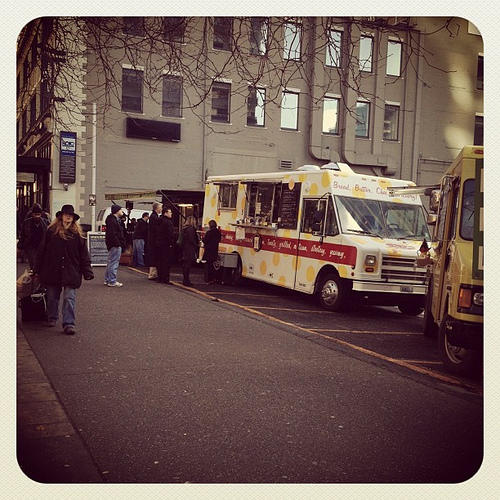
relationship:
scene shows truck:
[19, 19, 483, 483] [201, 163, 429, 315]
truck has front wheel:
[201, 163, 429, 315] [311, 277, 343, 311]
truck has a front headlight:
[201, 163, 429, 315] [364, 250, 378, 270]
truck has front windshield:
[201, 163, 429, 315] [333, 192, 421, 243]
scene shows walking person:
[19, 19, 483, 483] [37, 205, 92, 337]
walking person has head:
[37, 205, 92, 337] [58, 205, 77, 231]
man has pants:
[107, 206, 128, 290] [108, 250, 122, 283]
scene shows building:
[19, 19, 483, 483] [16, 17, 480, 243]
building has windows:
[16, 17, 480, 243] [112, 64, 405, 141]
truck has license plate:
[201, 163, 429, 315] [402, 286, 415, 298]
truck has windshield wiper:
[201, 163, 429, 315] [348, 228, 384, 238]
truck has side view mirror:
[201, 163, 429, 315] [314, 206, 326, 235]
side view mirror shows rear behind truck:
[314, 206, 326, 235] [201, 163, 429, 315]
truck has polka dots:
[201, 163, 429, 315] [255, 253, 289, 283]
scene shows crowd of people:
[19, 19, 483, 483] [105, 189, 219, 287]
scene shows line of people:
[19, 19, 483, 483] [105, 189, 219, 287]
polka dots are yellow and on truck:
[255, 253, 289, 283] [201, 163, 429, 315]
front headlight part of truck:
[364, 250, 378, 270] [201, 163, 429, 315]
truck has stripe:
[201, 163, 429, 315] [221, 224, 352, 266]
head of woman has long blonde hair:
[58, 205, 77, 231] [50, 222, 86, 245]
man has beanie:
[107, 206, 128, 290] [110, 206, 120, 216]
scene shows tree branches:
[19, 19, 483, 483] [63, 18, 465, 97]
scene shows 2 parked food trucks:
[19, 19, 483, 483] [199, 150, 484, 376]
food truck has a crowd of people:
[201, 163, 429, 315] [105, 189, 219, 287]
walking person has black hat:
[37, 205, 92, 337] [54, 203, 77, 218]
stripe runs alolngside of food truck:
[221, 224, 352, 266] [201, 163, 429, 315]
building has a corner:
[16, 17, 480, 243] [40, 23, 97, 243]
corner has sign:
[40, 23, 97, 243] [57, 132, 80, 185]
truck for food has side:
[201, 163, 429, 315] [204, 172, 341, 301]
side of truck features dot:
[204, 172, 341, 301] [307, 178, 319, 197]